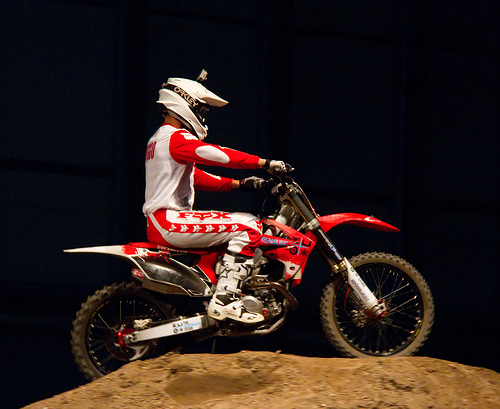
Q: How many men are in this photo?
A: One.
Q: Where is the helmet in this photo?
A: Man's head.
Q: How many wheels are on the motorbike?
A: Two.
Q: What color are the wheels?
A: Black.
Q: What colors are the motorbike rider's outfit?
A: Red, White.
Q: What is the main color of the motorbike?
A: Red.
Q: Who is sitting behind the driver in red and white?
A: No one.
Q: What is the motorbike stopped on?
A: Dirt.